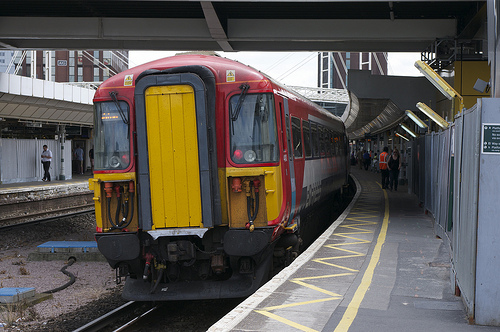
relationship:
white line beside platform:
[212, 197, 355, 329] [227, 138, 469, 330]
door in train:
[142, 87, 202, 227] [85, 48, 355, 308]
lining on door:
[198, 119, 208, 169] [138, 77, 208, 227]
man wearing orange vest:
[375, 144, 390, 188] [379, 152, 389, 170]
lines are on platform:
[242, 217, 392, 330] [226, 183, 463, 330]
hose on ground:
[40, 255, 79, 294] [0, 206, 124, 329]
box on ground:
[35, 239, 99, 253] [9, 237, 114, 324]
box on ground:
[1, 284, 39, 308] [9, 237, 114, 324]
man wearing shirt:
[41, 144, 53, 181] [40, 147, 53, 164]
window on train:
[226, 87, 279, 164] [85, 48, 355, 308]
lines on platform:
[258, 159, 390, 329] [211, 162, 467, 328]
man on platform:
[35, 145, 62, 180] [0, 172, 100, 233]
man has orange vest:
[41, 144, 53, 181] [379, 152, 389, 170]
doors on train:
[273, 106, 299, 207] [85, 48, 355, 308]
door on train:
[142, 87, 202, 227] [120, 70, 390, 235]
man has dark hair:
[41, 144, 53, 181] [39, 140, 48, 150]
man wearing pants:
[41, 144, 53, 181] [39, 162, 54, 183]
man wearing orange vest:
[378, 147, 390, 189] [373, 149, 391, 172]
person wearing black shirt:
[378, 144, 412, 191] [387, 155, 402, 170]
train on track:
[85, 48, 355, 308] [66, 282, 235, 327]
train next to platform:
[85, 48, 355, 308] [193, 158, 448, 323]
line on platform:
[262, 180, 393, 330] [211, 162, 467, 328]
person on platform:
[387, 148, 401, 192] [214, 173, 471, 330]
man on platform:
[41, 144, 53, 181] [0, 176, 95, 244]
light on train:
[238, 141, 259, 161] [85, 48, 355, 308]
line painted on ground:
[259, 305, 318, 330] [208, 155, 497, 327]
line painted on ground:
[294, 186, 402, 305] [253, 111, 431, 327]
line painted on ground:
[313, 252, 363, 262] [315, 228, 426, 330]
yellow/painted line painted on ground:
[286, 262, 393, 312] [226, 171, 446, 330]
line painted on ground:
[219, 192, 391, 329] [0, 218, 452, 330]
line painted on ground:
[362, 198, 402, 300] [369, 190, 448, 262]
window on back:
[226, 87, 279, 164] [83, 54, 297, 306]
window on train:
[226, 87, 279, 164] [74, 67, 309, 245]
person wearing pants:
[387, 148, 401, 192] [375, 169, 389, 189]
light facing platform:
[412, 59, 462, 113] [210, 151, 497, 328]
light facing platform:
[412, 98, 444, 134] [210, 151, 497, 328]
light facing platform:
[400, 107, 424, 133] [210, 151, 497, 328]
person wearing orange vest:
[387, 148, 401, 192] [379, 152, 389, 170]